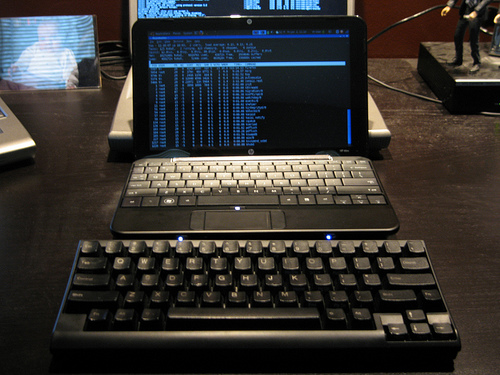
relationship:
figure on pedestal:
[440, 0, 490, 75] [415, 38, 498, 119]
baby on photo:
[7, 19, 82, 94] [0, 11, 104, 96]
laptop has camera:
[107, 15, 402, 238] [245, 17, 253, 26]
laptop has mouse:
[107, 15, 402, 238] [189, 207, 286, 236]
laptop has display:
[107, 15, 402, 238] [131, 15, 368, 153]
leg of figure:
[466, 12, 482, 75] [440, 0, 490, 75]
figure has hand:
[440, 0, 490, 75] [437, 6, 452, 19]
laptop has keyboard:
[107, 15, 402, 238] [47, 236, 462, 354]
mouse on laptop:
[189, 207, 286, 236] [107, 15, 402, 238]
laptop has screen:
[104, 1, 400, 150] [134, 0, 349, 20]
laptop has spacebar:
[104, 1, 400, 150] [165, 306, 321, 330]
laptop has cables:
[104, 1, 400, 150] [96, 38, 132, 84]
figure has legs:
[440, 0, 490, 75] [446, 10, 484, 74]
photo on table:
[0, 11, 104, 96] [1, 56, 498, 374]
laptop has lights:
[104, 1, 400, 150] [176, 232, 185, 244]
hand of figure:
[437, 6, 452, 19] [440, 0, 489, 73]